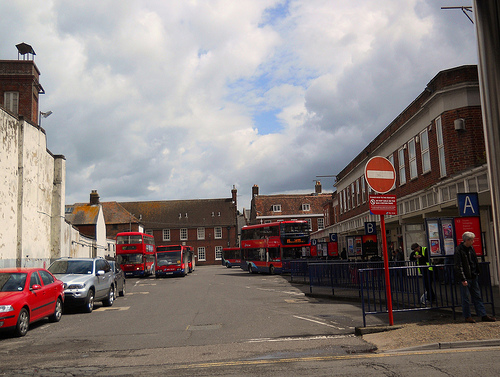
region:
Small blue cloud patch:
[260, 4, 292, 29]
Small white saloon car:
[1, 263, 66, 334]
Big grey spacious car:
[73, 253, 117, 313]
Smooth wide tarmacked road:
[169, 280, 240, 309]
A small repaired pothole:
[179, 316, 226, 333]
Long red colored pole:
[375, 213, 396, 319]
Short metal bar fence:
[311, 257, 373, 291]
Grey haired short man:
[461, 230, 478, 248]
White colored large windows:
[194, 227, 209, 264]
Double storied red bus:
[238, 219, 285, 273]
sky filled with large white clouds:
[58, 8, 214, 143]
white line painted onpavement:
[278, 300, 353, 334]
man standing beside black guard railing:
[450, 225, 492, 328]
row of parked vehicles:
[0, 259, 140, 336]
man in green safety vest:
[399, 231, 439, 296]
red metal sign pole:
[372, 218, 409, 333]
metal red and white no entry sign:
[360, 152, 400, 192]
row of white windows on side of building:
[158, 223, 243, 240]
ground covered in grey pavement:
[170, 288, 252, 342]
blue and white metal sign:
[450, 188, 483, 218]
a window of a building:
[416, 128, 434, 173]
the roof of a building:
[127, 199, 232, 222]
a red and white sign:
[362, 154, 401, 192]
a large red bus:
[112, 228, 159, 275]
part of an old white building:
[0, 111, 70, 266]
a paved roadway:
[27, 262, 369, 364]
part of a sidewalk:
[365, 320, 498, 352]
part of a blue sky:
[251, 110, 277, 130]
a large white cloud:
[304, 0, 474, 107]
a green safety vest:
[411, 245, 433, 272]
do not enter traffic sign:
[361, 163, 418, 225]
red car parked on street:
[8, 262, 67, 344]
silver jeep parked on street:
[52, 251, 114, 308]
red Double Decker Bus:
[234, 223, 311, 268]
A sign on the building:
[453, 188, 480, 213]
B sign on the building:
[362, 213, 377, 231]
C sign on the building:
[324, 226, 339, 246]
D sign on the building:
[311, 234, 320, 245]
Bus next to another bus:
[155, 238, 199, 281]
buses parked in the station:
[119, 223, 199, 279]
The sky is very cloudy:
[1, 6, 473, 193]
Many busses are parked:
[124, 211, 306, 287]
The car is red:
[5, 263, 61, 320]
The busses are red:
[137, 219, 292, 274]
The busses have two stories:
[247, 223, 288, 268]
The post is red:
[377, 207, 402, 322]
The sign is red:
[364, 154, 396, 194]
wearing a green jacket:
[415, 243, 432, 278]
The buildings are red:
[60, 114, 475, 284]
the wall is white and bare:
[0, 175, 63, 217]